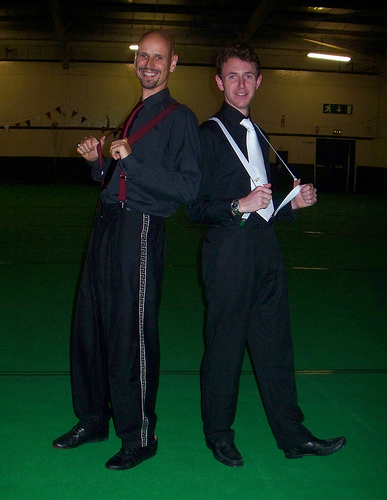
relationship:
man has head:
[51, 26, 199, 472] [131, 28, 180, 92]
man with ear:
[51, 26, 199, 472] [130, 49, 140, 71]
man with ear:
[51, 26, 199, 472] [170, 51, 178, 74]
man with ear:
[185, 40, 344, 470] [214, 75, 224, 91]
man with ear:
[185, 40, 344, 470] [254, 73, 265, 92]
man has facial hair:
[51, 26, 199, 472] [133, 64, 165, 91]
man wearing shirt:
[51, 26, 199, 472] [85, 86, 203, 219]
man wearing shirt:
[185, 40, 344, 470] [182, 102, 298, 223]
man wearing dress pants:
[51, 26, 199, 472] [65, 201, 166, 447]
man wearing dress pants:
[185, 40, 344, 470] [193, 222, 314, 446]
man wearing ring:
[51, 26, 199, 472] [75, 140, 81, 148]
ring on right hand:
[75, 140, 81, 148] [72, 133, 106, 160]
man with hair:
[185, 40, 344, 470] [213, 40, 260, 79]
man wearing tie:
[185, 40, 344, 470] [238, 115, 275, 224]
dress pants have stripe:
[65, 201, 166, 447] [133, 206, 154, 448]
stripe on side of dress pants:
[133, 206, 154, 448] [65, 201, 166, 447]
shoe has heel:
[278, 434, 348, 460] [285, 449, 306, 463]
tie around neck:
[238, 115, 275, 224] [222, 94, 253, 120]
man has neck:
[185, 40, 344, 470] [222, 94, 253, 120]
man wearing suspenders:
[51, 26, 199, 472] [92, 101, 181, 210]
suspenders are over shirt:
[92, 101, 181, 210] [85, 86, 203, 219]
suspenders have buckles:
[92, 101, 181, 210] [116, 170, 131, 212]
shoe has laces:
[105, 432, 160, 472] [118, 443, 137, 459]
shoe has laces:
[50, 417, 111, 449] [68, 421, 84, 437]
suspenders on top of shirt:
[92, 101, 181, 210] [85, 86, 203, 219]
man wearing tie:
[51, 26, 199, 472] [111, 101, 143, 154]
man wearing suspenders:
[185, 40, 344, 470] [205, 112, 303, 226]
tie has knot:
[238, 115, 275, 224] [239, 116, 254, 134]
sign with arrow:
[332, 102, 344, 115] [335, 104, 342, 113]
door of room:
[313, 134, 358, 193] [1, 0, 384, 498]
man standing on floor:
[51, 26, 199, 472] [1, 183, 385, 499]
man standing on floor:
[185, 40, 344, 470] [1, 183, 385, 499]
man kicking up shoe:
[185, 40, 344, 470] [278, 434, 348, 460]